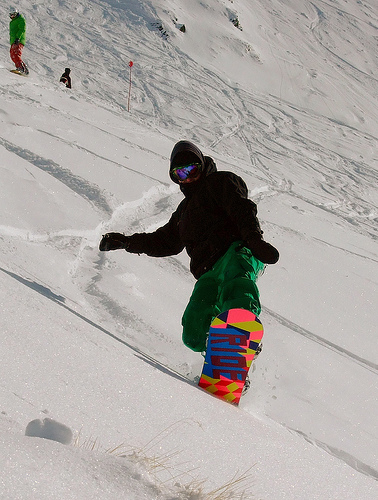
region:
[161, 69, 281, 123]
snow littered with snow board tracks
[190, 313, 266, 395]
a multi colored snow board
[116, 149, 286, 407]
a snow boarder wearing a goggles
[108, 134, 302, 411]
a man in a black winter jacket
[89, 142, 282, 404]
a man in black mittens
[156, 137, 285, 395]
a man in green pants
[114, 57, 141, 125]
a red flag posted in the snow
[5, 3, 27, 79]
a man in a green jacket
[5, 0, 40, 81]
a man in red pants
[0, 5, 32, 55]
a man in a white helmet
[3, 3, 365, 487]
people on slope of snow-covered mountain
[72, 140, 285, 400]
curved trail of snow behind snowboarder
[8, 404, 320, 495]
tan blades of grass in untouched glistening snow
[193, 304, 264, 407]
colorful mosaic under board with word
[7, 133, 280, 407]
thin shadow to side of snowboarder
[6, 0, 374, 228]
marks made in snow by winter athletes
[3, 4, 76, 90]
two people going in opposite directions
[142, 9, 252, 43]
rough edges of rock peeking through snow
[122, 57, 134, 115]
pole with orange symbol on top stuck into snow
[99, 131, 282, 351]
snowboarder in dark jacket and green pants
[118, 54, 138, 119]
a red sign in the snow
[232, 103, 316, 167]
snow boarding tracks in the snow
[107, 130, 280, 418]
a man in a black jacket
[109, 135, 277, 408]
a man in black gloves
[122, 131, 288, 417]
a man riding a snow board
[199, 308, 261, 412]
a snow board with a lot of colors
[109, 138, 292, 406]
a man wearing protective goggles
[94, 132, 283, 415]
skier on snow slope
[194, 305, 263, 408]
multi colored snow board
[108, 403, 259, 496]
tall yellow grass poking through snow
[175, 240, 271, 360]
green snow pants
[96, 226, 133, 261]
black glove on hand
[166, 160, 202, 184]
goggles on skier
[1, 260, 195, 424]
shadow on snow slope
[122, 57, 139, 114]
orange pole in snow slope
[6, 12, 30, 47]
green snow coat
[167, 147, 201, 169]
hat on skier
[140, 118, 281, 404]
xnowboarder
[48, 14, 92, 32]
white clouds in blue sky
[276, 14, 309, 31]
white clouds in blue sky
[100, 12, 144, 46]
white clouds in blue sky